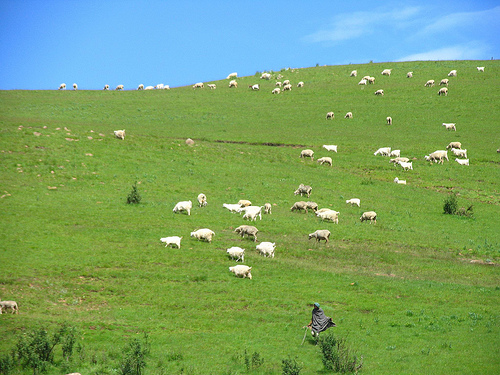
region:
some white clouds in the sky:
[323, 5, 483, 63]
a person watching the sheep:
[302, 297, 334, 340]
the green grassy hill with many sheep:
[0, 55, 495, 373]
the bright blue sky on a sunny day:
[1, 0, 477, 88]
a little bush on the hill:
[124, 182, 141, 202]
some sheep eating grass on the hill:
[153, 180, 385, 285]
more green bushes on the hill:
[7, 325, 156, 373]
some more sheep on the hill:
[218, 62, 464, 127]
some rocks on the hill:
[12, 120, 104, 195]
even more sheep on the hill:
[286, 135, 473, 177]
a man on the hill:
[287, 295, 345, 355]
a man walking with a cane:
[277, 302, 340, 354]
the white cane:
[296, 324, 311, 349]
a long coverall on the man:
[306, 306, 338, 338]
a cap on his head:
[308, 297, 326, 310]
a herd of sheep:
[88, 67, 488, 279]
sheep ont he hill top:
[49, 69, 170, 89]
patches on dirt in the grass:
[49, 259, 111, 330]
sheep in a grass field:
[138, 92, 433, 294]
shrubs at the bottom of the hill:
[9, 325, 173, 373]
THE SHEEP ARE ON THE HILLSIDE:
[0, 64, 486, 320]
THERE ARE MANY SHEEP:
[0, 59, 487, 321]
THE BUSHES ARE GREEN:
[1, 317, 372, 373]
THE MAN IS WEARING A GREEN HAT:
[294, 297, 339, 349]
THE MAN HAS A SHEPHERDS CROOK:
[295, 296, 344, 351]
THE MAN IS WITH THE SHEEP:
[0, 53, 499, 373]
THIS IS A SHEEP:
[156, 230, 183, 254]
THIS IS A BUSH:
[121, 180, 144, 208]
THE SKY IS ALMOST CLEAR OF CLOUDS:
[0, 0, 499, 106]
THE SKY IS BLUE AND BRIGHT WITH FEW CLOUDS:
[0, 0, 499, 105]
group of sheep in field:
[75, 81, 494, 328]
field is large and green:
[42, 62, 498, 364]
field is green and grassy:
[59, 109, 464, 371]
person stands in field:
[302, 277, 342, 344]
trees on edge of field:
[8, 343, 220, 372]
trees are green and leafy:
[2, 323, 204, 373]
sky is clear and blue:
[6, 13, 110, 51]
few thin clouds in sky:
[340, 22, 497, 62]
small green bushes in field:
[122, 178, 146, 218]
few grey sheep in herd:
[282, 193, 332, 250]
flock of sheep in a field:
[53, 68, 485, 300]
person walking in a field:
[297, 297, 335, 349]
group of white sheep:
[171, 189, 291, 274]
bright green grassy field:
[29, 74, 486, 330]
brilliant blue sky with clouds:
[26, 2, 497, 88]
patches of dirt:
[2, 254, 147, 331]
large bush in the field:
[440, 191, 473, 223]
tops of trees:
[9, 314, 347, 373]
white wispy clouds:
[318, 5, 493, 70]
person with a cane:
[296, 303, 333, 344]